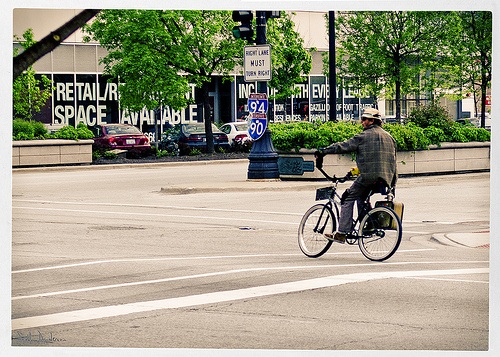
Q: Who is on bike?
A: The man.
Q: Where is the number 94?
A: On the traffic sign.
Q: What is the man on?
A: A bicycle.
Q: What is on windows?
A: Painted advertisement.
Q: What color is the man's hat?
A: White.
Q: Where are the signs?
A: On the traffic light.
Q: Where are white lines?
A: On the ground.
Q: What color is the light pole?
A: Blue.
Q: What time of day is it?
A: The afternoon.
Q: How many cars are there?
A: Three.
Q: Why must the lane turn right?
A: It's the law.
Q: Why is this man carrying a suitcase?
A: To carry his belonging.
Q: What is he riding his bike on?
A: Concrete.